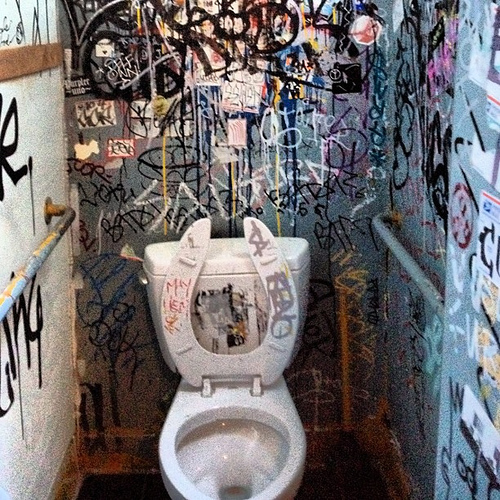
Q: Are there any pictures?
A: No, there are no pictures.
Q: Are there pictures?
A: No, there are no pictures.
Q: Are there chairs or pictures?
A: No, there are no pictures or chairs.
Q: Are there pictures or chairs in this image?
A: No, there are no pictures or chairs.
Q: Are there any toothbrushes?
A: No, there are no toothbrushes.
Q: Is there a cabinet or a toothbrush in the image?
A: No, there are no toothbrushes or cabinets.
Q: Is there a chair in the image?
A: No, there are no chairs.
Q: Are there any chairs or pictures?
A: No, there are no chairs or pictures.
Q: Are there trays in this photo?
A: No, there are no trays.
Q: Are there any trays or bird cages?
A: No, there are no trays or bird cages.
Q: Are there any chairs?
A: No, there are no chairs.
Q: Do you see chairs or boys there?
A: No, there are no chairs or boys.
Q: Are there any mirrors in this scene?
A: No, there are no mirrors.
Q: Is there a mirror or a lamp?
A: No, there are no mirrors or lamps.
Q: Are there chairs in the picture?
A: No, there are no chairs.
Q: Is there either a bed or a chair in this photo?
A: No, there are no chairs or beds.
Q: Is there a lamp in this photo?
A: No, there are no lamps.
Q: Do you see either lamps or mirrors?
A: No, there are no lamps or mirrors.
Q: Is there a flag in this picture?
A: No, there are no flags.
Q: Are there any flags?
A: No, there are no flags.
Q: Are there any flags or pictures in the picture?
A: No, there are no flags or pictures.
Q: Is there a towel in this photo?
A: No, there are no towels.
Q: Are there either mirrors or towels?
A: No, there are no towels or mirrors.